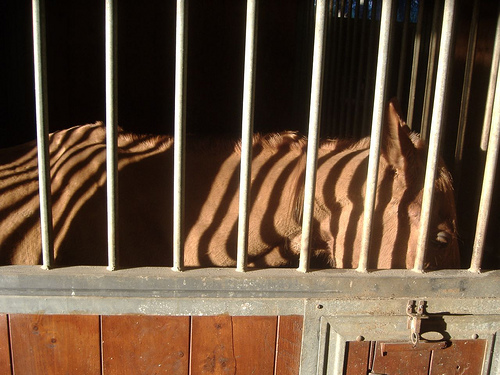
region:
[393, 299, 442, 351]
Latch on door.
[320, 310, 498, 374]
door in enclosure.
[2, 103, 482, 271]
Horse behind the bars.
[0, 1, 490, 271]
Metal bars on the enclosure.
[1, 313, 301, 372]
Wood on the side of the enclosure.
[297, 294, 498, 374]
Metal frame around the door.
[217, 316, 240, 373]
Crack in the wood.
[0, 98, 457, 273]
Shadows on the horse.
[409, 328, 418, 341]
Hole in the latch.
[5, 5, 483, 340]
a horse in a horse stall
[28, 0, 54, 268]
the metal bar of a horse stall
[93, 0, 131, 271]
the metal bar of a horse stall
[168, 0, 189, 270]
the metal bar of a horse stall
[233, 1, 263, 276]
the metal bar of a horse stall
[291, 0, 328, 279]
the metal bar of a horse stall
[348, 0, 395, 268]
the metal bar of a horse stall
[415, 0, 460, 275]
the metal bar of a horse stall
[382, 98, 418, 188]
the ear of a horse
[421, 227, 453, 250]
the eye of a horse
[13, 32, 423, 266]
bars across the top of the stall wall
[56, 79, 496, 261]
horse in the stall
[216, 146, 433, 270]
shadow of the bars on the horse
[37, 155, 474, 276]
brown horse in a stall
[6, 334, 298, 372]
wooden stall wall in a stable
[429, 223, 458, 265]
eye of the horse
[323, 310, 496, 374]
small door for feed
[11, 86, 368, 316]
horse is in a stall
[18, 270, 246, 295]
metal rail over the top of the wall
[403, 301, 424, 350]
latch for the small door